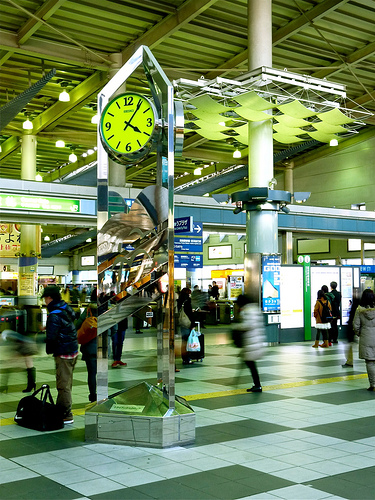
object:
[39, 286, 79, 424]
person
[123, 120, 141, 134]
hand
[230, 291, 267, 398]
person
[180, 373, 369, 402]
stripe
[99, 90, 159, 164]
clock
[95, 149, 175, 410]
stand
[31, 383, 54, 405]
straps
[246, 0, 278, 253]
pillar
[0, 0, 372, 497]
building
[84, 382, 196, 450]
base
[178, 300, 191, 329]
bag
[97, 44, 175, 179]
arrow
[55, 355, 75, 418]
legs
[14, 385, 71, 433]
bag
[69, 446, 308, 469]
ground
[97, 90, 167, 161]
clock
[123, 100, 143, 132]
minute hand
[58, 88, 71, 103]
bulb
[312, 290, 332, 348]
people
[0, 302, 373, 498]
floor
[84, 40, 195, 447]
glass stand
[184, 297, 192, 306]
shoulder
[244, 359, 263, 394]
leg